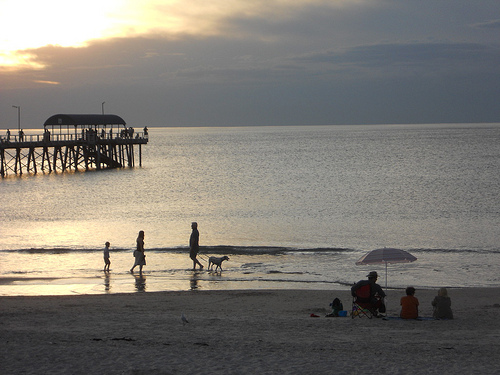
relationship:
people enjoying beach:
[292, 260, 462, 329] [194, 309, 252, 369]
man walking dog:
[186, 215, 202, 284] [207, 254, 235, 282]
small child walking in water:
[98, 241, 115, 274] [158, 166, 223, 205]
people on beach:
[292, 260, 462, 329] [194, 309, 252, 369]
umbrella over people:
[354, 246, 428, 265] [292, 260, 462, 329]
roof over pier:
[55, 114, 138, 126] [8, 105, 162, 180]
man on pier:
[139, 126, 153, 142] [8, 105, 162, 180]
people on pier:
[10, 128, 155, 148] [8, 105, 162, 180]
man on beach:
[186, 215, 202, 284] [194, 309, 252, 369]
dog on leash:
[207, 254, 235, 282] [199, 250, 211, 267]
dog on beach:
[207, 254, 235, 282] [194, 309, 252, 369]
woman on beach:
[125, 233, 168, 286] [194, 309, 252, 369]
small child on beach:
[98, 241, 115, 274] [194, 309, 252, 369]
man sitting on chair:
[349, 270, 388, 324] [353, 300, 386, 315]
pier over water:
[8, 105, 162, 180] [158, 166, 223, 205]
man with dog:
[186, 215, 202, 284] [207, 254, 235, 282]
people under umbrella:
[292, 260, 462, 329] [354, 246, 428, 265]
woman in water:
[125, 233, 168, 286] [158, 166, 223, 205]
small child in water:
[98, 241, 115, 274] [158, 166, 223, 205]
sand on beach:
[428, 356, 478, 366] [194, 309, 252, 369]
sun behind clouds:
[33, 20, 135, 49] [175, 7, 298, 67]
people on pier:
[292, 260, 462, 329] [8, 105, 162, 180]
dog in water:
[207, 254, 235, 282] [158, 166, 223, 205]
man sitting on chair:
[186, 215, 202, 284] [353, 300, 386, 315]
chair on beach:
[353, 300, 386, 315] [194, 309, 252, 369]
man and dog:
[186, 215, 202, 284] [207, 254, 235, 282]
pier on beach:
[8, 105, 162, 180] [194, 309, 252, 369]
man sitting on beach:
[186, 215, 202, 284] [234, 306, 289, 338]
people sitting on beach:
[292, 260, 462, 329] [194, 309, 252, 369]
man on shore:
[186, 215, 202, 284] [457, 275, 496, 305]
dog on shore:
[207, 254, 235, 282] [457, 275, 496, 305]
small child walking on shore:
[98, 241, 115, 274] [457, 275, 496, 305]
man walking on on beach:
[186, 215, 202, 284] [234, 306, 289, 338]